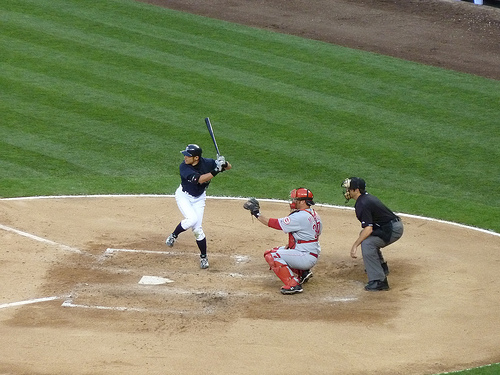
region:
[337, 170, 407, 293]
an umpire watching the pitch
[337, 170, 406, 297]
an umpire wearing black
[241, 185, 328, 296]
a catcher is squatting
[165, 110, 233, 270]
a batter with a black bat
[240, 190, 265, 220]
a catcher with a black catcher's mitt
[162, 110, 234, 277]
a batter wearing a blue and white uniform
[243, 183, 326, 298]
a catcher wearing a gray and red uniform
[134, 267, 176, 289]
a white home plate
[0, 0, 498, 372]
a baseball field with green grass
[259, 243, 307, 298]
a catcher wearing red shin guards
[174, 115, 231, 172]
the head of a man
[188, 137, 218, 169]
the ear of a man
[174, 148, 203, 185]
the face of a man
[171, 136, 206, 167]
the nose of a man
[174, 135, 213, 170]
the eye of a man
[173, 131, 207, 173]
the chin of a man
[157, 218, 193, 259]
the foot of a man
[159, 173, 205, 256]
the leg of a man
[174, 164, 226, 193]
the arm of a man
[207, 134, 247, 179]
the hand of a man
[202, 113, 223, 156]
a black bat in a man's hands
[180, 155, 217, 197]
a navy shirt on a man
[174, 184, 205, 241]
white pants on a man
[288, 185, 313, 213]
a red catcher's mask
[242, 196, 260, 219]
a black mitt on a catcher's hand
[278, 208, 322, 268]
a grey uniform on a catcher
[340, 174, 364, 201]
a black mask on an umpire's face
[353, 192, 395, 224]
a black shirt on an umpire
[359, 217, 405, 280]
grey pants on an umpire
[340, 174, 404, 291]
an umpire behind a catcher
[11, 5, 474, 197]
grass on the baseball field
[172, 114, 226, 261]
a man swinging a baseball bat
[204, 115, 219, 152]
the baseball bat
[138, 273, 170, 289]
the home plate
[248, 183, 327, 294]
the catcher of the baseball game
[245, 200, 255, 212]
the catchers mitt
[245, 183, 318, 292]
a man wearing a red helmet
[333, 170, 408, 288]
a man wearing a black helmet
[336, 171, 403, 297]
a man wearing a black shirt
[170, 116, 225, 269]
the player ready to bat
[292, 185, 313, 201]
he is wearing a red helmet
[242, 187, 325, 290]
the catcher ready to carch the ball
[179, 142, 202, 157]
this cap is blue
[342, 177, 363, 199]
the head of the man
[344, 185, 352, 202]
a metal protective mask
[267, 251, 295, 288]
this leg protector is red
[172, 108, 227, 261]
the player is swinging the bat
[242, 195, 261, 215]
the glove of the catcher